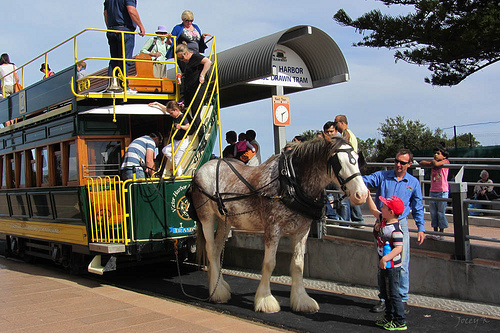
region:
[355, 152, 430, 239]
the shirt is blue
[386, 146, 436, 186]
the man is wearing sunglasses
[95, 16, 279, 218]
the people are descending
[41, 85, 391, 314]
the horse is white and brown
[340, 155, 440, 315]
the kid is petting the horse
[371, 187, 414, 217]
the cap is red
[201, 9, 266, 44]
the sky is blue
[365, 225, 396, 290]
the tumbler is blue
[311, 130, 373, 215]
the horse has covers on its eyes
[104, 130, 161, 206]
the shirt is stripes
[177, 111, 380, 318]
cream and brown horse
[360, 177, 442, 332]
boy petting horse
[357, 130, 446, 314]
man petting horse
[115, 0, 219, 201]
people going down stairs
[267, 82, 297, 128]
clock on pole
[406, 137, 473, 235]
boy leaning on rails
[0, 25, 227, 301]
green and yellow rail carriage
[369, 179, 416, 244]
boy wearing red cap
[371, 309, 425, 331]
boy wearing green and black sneakers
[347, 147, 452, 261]
man wearing blue shirt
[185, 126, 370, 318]
small white and grey horse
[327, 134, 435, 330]
young boy petting horse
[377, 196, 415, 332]
young boy holding drink bottle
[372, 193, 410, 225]
boy in red baseball cap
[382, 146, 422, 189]
man wearing sunglasses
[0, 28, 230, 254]
double decker bus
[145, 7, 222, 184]
people walking down stairs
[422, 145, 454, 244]
child leaning on railing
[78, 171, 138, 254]
yellow metal gate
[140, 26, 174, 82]
person in purple hat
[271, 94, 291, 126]
train departure time sign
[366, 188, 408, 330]
young boy petting horse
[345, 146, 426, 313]
man touching horse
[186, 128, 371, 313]
horse with halter for pulling tram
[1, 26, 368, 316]
horse drawn tram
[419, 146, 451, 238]
young child leaning on the fence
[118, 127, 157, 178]
man with blue and white striped shirt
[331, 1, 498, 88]
branches of overhanging tree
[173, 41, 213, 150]
woman descending stairs of the tram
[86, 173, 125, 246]
yellow guard rail on tram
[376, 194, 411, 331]
Boy with the red hat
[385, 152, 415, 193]
Man wearing sun shades and a blue shirt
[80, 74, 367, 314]
green and yellow horse drawn tram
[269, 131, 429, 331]
A boy and man petting a horse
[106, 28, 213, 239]
people walking down the tram stairs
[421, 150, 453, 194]
little girl wearing a pink shirt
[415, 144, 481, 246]
little girl standing on tram platform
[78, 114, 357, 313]
Clydesdale pulling a Double Decker tram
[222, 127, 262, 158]
people waiting to get on the tram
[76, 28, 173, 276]
brown bench seating on the second floor of the tram